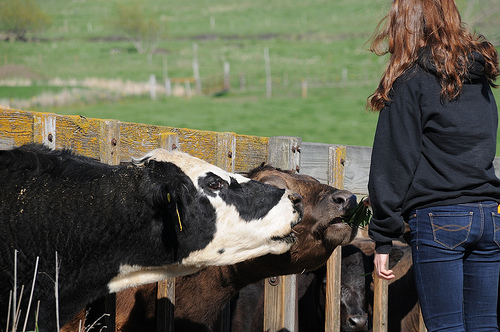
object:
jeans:
[406, 197, 497, 331]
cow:
[234, 245, 404, 330]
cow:
[69, 167, 365, 327]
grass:
[2, 3, 499, 152]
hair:
[367, 0, 496, 111]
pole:
[261, 253, 298, 331]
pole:
[323, 242, 340, 330]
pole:
[373, 245, 388, 330]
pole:
[157, 276, 175, 331]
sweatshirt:
[367, 47, 499, 259]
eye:
[203, 176, 225, 193]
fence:
[1, 106, 376, 198]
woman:
[364, 2, 499, 330]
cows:
[1, 144, 404, 331]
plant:
[345, 194, 374, 243]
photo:
[1, 2, 497, 330]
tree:
[110, 3, 161, 61]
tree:
[0, 2, 53, 42]